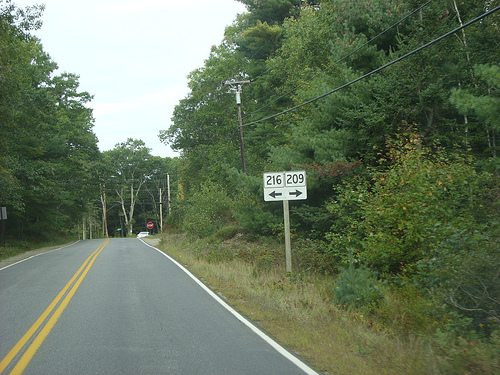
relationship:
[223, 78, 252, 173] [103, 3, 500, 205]
pole has wires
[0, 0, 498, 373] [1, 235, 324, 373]
trees along road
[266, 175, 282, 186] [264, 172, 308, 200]
216 on sign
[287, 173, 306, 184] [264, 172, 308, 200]
209 on sign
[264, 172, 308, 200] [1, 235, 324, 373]
sign next to road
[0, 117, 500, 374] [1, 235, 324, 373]
bushes around road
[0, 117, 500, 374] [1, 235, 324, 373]
bushes near road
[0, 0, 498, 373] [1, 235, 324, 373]
trees near road